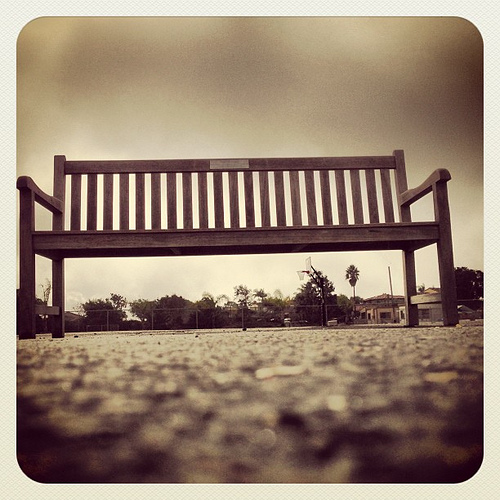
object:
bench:
[15, 150, 460, 339]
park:
[15, 17, 482, 484]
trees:
[452, 265, 483, 300]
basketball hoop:
[298, 268, 310, 279]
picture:
[0, 0, 499, 499]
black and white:
[1, 0, 498, 497]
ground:
[17, 323, 484, 485]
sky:
[17, 17, 484, 295]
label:
[209, 159, 249, 171]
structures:
[353, 289, 406, 324]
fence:
[68, 306, 367, 331]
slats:
[67, 173, 81, 233]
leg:
[437, 242, 458, 325]